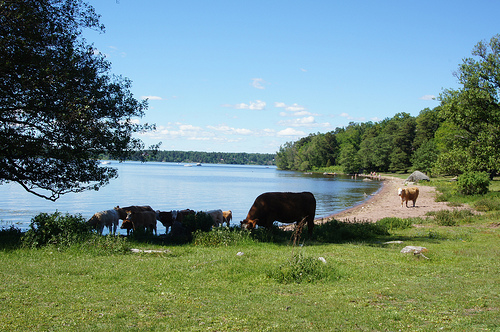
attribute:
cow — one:
[238, 189, 324, 246]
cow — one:
[238, 190, 316, 243]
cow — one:
[245, 191, 322, 235]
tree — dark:
[0, 0, 158, 201]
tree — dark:
[428, 41, 498, 191]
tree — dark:
[408, 107, 434, 175]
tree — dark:
[388, 112, 409, 174]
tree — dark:
[341, 141, 359, 176]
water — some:
[0, 157, 377, 237]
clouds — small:
[160, 62, 331, 141]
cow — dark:
[237, 187, 322, 243]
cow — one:
[245, 187, 319, 239]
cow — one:
[238, 188, 322, 233]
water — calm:
[3, 160, 384, 230]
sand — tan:
[365, 205, 402, 215]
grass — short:
[0, 174, 499, 329]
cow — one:
[392, 182, 427, 211]